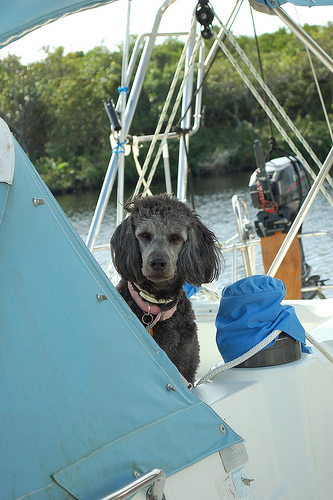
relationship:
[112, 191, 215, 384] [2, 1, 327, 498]
dog in boat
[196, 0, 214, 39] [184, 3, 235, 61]
pulley has rope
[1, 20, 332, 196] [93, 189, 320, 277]
green trees behind water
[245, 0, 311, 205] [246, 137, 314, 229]
rope holds motor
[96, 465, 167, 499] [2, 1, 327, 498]
hand railing on boat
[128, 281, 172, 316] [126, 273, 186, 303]
collar on neck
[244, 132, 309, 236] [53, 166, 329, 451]
motor back boat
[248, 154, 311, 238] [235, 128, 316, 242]
motor on motor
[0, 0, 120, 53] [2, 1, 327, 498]
awning on boat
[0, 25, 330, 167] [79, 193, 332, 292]
greenery side water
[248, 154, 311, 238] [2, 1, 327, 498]
motor on boat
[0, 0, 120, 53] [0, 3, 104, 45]
awning with trim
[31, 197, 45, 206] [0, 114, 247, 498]
attachment on canvas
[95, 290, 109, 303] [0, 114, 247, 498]
attachment on canvas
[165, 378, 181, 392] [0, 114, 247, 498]
attachment on canvas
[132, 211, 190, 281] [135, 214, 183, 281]
dog's face with hair